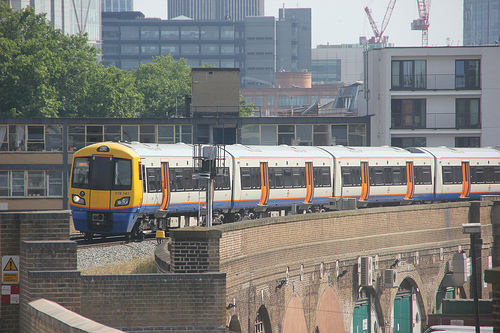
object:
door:
[393, 296, 411, 333]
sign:
[0, 254, 20, 284]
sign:
[1, 284, 19, 304]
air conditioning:
[382, 267, 399, 288]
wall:
[0, 198, 499, 333]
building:
[3, 0, 103, 61]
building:
[103, 0, 133, 13]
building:
[102, 10, 243, 85]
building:
[165, 1, 264, 19]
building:
[276, 8, 311, 72]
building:
[366, 45, 500, 146]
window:
[390, 100, 426, 128]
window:
[455, 96, 471, 127]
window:
[390, 60, 425, 89]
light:
[70, 194, 83, 204]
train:
[65, 140, 499, 241]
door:
[303, 162, 313, 202]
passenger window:
[239, 167, 265, 187]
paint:
[70, 205, 140, 234]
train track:
[75, 233, 156, 247]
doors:
[352, 300, 370, 333]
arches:
[383, 261, 431, 333]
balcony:
[387, 59, 427, 93]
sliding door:
[392, 60, 425, 90]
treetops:
[0, 4, 94, 120]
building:
[0, 115, 367, 210]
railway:
[16, 198, 500, 330]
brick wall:
[19, 210, 223, 333]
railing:
[393, 74, 479, 90]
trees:
[83, 61, 147, 117]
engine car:
[66, 141, 235, 236]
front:
[64, 139, 141, 234]